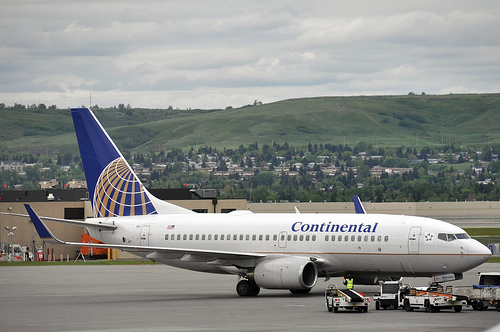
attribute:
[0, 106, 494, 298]
plane — white, whtie, blue, preparing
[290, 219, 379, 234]
logo — blue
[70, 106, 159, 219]
tail — blue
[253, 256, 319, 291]
engine — white, large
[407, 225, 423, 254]
door — white, large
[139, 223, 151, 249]
back door — whtie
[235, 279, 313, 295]
tires — black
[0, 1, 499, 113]
sky — cloudy, cloud